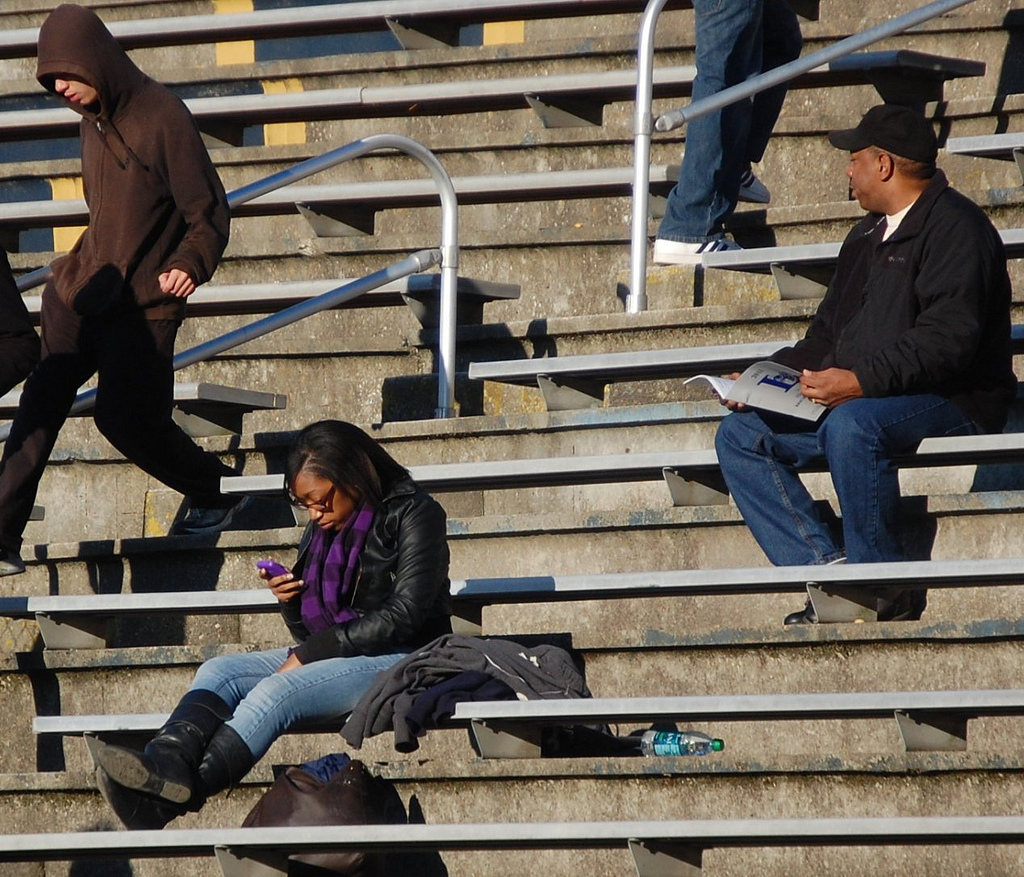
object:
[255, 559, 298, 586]
cellphone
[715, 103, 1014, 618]
boy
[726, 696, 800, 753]
bleacher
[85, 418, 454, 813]
lady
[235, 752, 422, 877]
bag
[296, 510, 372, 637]
scraf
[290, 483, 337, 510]
glasses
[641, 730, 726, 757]
bottle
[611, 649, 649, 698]
ground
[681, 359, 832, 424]
books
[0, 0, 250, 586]
lady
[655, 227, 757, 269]
shoes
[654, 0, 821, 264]
person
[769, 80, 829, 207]
stairs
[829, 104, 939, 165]
cap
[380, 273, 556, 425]
shadow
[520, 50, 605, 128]
stairs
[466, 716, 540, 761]
handbag